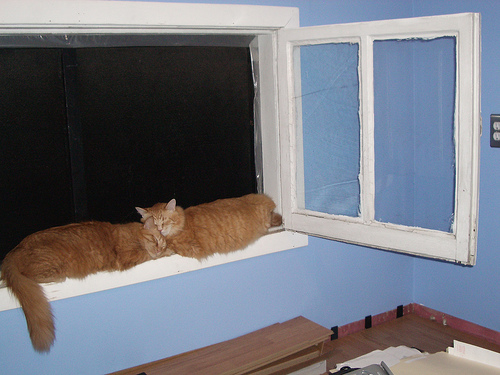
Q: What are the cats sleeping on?
A: The window sill.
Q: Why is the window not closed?
A: The cats are sleeping on the sill.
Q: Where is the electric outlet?
A: On the right side wall.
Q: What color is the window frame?
A: White.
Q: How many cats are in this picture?
A: Two.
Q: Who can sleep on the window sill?
A: The cats.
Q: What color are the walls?
A: Blue.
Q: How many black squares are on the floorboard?
A: Three.